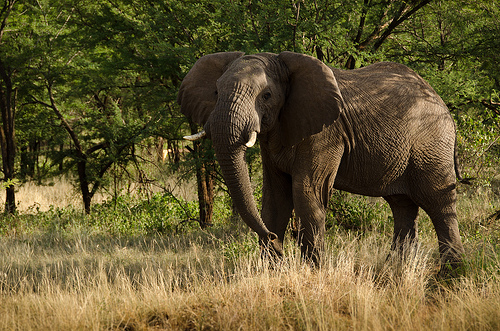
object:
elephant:
[174, 42, 476, 280]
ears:
[272, 52, 344, 148]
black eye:
[260, 91, 273, 101]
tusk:
[181, 130, 208, 142]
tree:
[25, 52, 152, 214]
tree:
[119, 1, 245, 239]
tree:
[405, 0, 500, 186]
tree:
[0, 2, 26, 221]